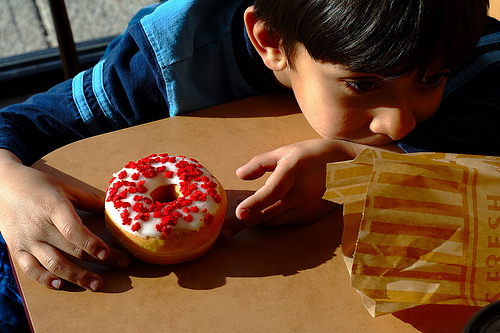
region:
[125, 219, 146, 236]
Red sprinkle on doughnut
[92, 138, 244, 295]
Doughbut sitting on table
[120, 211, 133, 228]
Red sprinkle on doughnut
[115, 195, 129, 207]
Red sprinkle on doughnut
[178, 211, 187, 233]
Red sprinkle on doughnut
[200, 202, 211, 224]
Red sprinkle on doughnut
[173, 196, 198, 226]
Red sprinkle on doughnut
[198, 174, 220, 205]
Red sprinkle on doughnut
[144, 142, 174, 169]
Red sprinkle on doughnut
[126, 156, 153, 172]
Red sprinkle on doughnut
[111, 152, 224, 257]
donut with white frosting and red sprinkles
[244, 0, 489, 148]
little boy with dark hair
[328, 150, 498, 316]
open paper bag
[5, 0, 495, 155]
boy wearing a blue shirt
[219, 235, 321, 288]
shadows being cast on the table from the sun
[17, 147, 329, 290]
little boy's hands near the donut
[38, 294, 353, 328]
brown tabletop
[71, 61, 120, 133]
light blue stripes on a dark blue shirt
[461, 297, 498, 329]
top of a coffee cup lid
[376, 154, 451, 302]
stripes on a paper bag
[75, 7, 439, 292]
boy with dark hair has his face on a table with a donut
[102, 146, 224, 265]
donut with white frosting and red spinkles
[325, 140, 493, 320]
brown paper bag with red stripes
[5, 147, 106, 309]
the boy's left hand touching the donut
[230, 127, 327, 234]
the boy's right hand reaching for the donut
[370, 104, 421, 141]
the boy's nose with a shadow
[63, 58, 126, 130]
two light blue stripes on the arm of the boy's blue shirt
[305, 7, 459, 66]
the boy's shiny, black, straight hair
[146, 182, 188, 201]
hole in the middle of the donut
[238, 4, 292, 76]
the boy's right ear on his head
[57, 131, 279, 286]
Donut on the table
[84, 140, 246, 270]
Plain donut with frosting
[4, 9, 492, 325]
Child with a donut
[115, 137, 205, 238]
Red sprinkles on the donut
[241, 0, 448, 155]
The child's face is on the table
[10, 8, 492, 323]
Photo taken during the day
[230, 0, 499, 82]
The boy is brunette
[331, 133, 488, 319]
Paper bag from the donut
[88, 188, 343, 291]
Shadow cast on the table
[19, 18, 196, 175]
Blue shirt on the boy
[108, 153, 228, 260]
A tasty looking cake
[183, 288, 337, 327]
Clean smooth brown table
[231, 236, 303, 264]
A dark cake shadow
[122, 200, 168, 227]
Red and white icing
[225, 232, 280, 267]
A dark black shadow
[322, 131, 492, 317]
Brown stripped paper bag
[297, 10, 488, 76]
Black short rough hair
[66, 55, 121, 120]
Two sky blue stripes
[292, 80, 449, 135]
A white smooth face